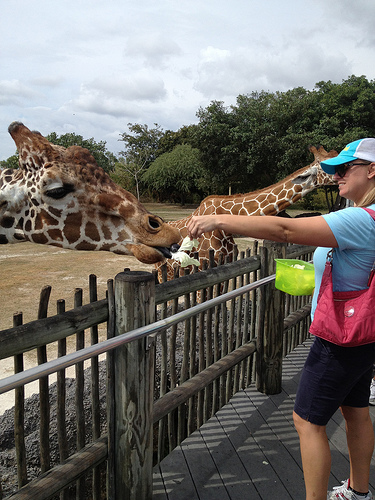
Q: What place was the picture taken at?
A: It was taken at the forest.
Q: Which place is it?
A: It is a forest.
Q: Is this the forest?
A: Yes, it is the forest.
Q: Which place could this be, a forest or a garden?
A: It is a forest.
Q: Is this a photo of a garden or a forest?
A: It is showing a forest.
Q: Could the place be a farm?
A: No, it is a forest.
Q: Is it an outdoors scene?
A: Yes, it is outdoors.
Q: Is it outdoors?
A: Yes, it is outdoors.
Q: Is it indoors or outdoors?
A: It is outdoors.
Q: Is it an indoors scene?
A: No, it is outdoors.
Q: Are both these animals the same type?
A: Yes, all the animals are giraffes.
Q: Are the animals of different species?
A: No, all the animals are giraffes.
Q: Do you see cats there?
A: No, there are no cats.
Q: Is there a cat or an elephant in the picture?
A: No, there are no cats or elephants.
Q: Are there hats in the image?
A: Yes, there is a hat.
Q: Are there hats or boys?
A: Yes, there is a hat.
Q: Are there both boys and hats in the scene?
A: No, there is a hat but no boys.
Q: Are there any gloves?
A: No, there are no gloves.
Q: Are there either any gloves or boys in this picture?
A: No, there are no gloves or boys.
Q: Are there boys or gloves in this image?
A: No, there are no gloves or boys.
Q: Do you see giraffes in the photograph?
A: Yes, there is a giraffe.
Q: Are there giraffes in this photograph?
A: Yes, there is a giraffe.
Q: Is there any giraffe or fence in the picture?
A: Yes, there is a giraffe.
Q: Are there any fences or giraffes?
A: Yes, there is a giraffe.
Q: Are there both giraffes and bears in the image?
A: No, there is a giraffe but no bears.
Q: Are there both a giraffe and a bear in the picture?
A: No, there is a giraffe but no bears.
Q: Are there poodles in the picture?
A: No, there are no poodles.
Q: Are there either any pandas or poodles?
A: No, there are no poodles or pandas.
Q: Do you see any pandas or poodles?
A: No, there are no poodles or pandas.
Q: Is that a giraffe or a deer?
A: That is a giraffe.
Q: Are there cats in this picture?
A: No, there are no cats.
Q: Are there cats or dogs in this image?
A: No, there are no cats or dogs.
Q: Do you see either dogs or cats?
A: No, there are no cats or dogs.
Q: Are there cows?
A: No, there are no cows.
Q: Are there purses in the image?
A: Yes, there is a purse.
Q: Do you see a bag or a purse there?
A: Yes, there is a purse.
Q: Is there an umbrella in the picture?
A: No, there are no umbrellas.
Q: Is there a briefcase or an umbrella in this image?
A: No, there are no umbrellas or briefcases.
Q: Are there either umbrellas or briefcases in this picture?
A: No, there are no umbrellas or briefcases.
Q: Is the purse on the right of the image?
A: Yes, the purse is on the right of the image.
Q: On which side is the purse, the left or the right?
A: The purse is on the right of the image.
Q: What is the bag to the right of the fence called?
A: The bag is a purse.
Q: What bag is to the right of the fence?
A: The bag is a purse.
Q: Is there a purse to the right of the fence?
A: Yes, there is a purse to the right of the fence.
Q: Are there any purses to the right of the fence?
A: Yes, there is a purse to the right of the fence.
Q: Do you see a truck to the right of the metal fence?
A: No, there is a purse to the right of the fence.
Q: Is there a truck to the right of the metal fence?
A: No, there is a purse to the right of the fence.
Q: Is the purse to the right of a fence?
A: Yes, the purse is to the right of a fence.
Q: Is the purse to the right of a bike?
A: No, the purse is to the right of a fence.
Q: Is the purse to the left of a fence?
A: No, the purse is to the right of a fence.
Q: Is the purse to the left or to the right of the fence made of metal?
A: The purse is to the right of the fence.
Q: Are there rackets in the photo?
A: No, there are no rackets.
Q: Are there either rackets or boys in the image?
A: No, there are no rackets or boys.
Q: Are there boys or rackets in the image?
A: No, there are no rackets or boys.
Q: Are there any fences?
A: Yes, there is a fence.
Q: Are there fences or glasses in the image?
A: Yes, there is a fence.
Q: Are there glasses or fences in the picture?
A: Yes, there is a fence.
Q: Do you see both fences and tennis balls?
A: No, there is a fence but no tennis balls.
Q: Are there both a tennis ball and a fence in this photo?
A: No, there is a fence but no tennis balls.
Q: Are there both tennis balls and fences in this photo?
A: No, there is a fence but no tennis balls.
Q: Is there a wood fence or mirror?
A: Yes, there is a wood fence.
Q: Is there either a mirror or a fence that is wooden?
A: Yes, the fence is wooden.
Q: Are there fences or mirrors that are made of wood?
A: Yes, the fence is made of wood.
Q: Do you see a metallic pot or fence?
A: Yes, there is a metal fence.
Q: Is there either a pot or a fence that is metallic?
A: Yes, the fence is metallic.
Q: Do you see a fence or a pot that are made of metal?
A: Yes, the fence is made of metal.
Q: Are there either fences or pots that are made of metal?
A: Yes, the fence is made of metal.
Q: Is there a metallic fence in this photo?
A: Yes, there is a metal fence.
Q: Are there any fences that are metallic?
A: Yes, there is a fence that is metallic.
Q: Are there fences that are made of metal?
A: Yes, there is a fence that is made of metal.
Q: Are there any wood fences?
A: Yes, there is a wood fence.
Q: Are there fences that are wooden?
A: Yes, there is a fence that is wooden.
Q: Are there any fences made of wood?
A: Yes, there is a fence that is made of wood.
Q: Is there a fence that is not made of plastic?
A: Yes, there is a fence that is made of wood.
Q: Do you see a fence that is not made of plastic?
A: Yes, there is a fence that is made of wood.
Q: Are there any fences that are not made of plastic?
A: Yes, there is a fence that is made of wood.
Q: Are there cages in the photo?
A: No, there are no cages.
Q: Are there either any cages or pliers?
A: No, there are no cages or pliers.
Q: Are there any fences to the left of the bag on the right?
A: Yes, there is a fence to the left of the purse.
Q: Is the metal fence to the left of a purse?
A: Yes, the fence is to the left of a purse.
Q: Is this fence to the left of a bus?
A: No, the fence is to the left of a purse.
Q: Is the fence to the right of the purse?
A: No, the fence is to the left of the purse.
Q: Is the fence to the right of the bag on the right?
A: No, the fence is to the left of the purse.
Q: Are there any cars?
A: No, there are no cars.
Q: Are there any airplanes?
A: No, there are no airplanes.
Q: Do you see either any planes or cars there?
A: No, there are no planes or cars.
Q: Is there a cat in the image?
A: No, there are no cats.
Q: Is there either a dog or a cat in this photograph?
A: No, there are no cats or dogs.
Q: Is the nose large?
A: Yes, the nose is large.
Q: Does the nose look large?
A: Yes, the nose is large.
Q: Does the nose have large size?
A: Yes, the nose is large.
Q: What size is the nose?
A: The nose is large.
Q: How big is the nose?
A: The nose is large.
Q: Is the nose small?
A: No, the nose is large.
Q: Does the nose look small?
A: No, the nose is large.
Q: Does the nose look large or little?
A: The nose is large.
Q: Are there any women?
A: Yes, there is a woman.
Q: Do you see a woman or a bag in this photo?
A: Yes, there is a woman.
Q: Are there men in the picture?
A: No, there are no men.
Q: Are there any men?
A: No, there are no men.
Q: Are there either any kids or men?
A: No, there are no men or kids.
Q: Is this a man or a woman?
A: This is a woman.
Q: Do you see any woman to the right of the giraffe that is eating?
A: Yes, there is a woman to the right of the giraffe.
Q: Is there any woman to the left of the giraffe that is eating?
A: No, the woman is to the right of the giraffe.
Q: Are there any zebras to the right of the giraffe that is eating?
A: No, there is a woman to the right of the giraffe.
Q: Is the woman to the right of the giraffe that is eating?
A: Yes, the woman is to the right of the giraffe.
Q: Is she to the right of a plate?
A: No, the woman is to the right of the giraffe.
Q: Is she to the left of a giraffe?
A: No, the woman is to the right of a giraffe.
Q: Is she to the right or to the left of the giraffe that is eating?
A: The woman is to the right of the giraffe.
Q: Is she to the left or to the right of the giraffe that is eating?
A: The woman is to the right of the giraffe.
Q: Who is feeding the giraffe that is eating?
A: The woman is feeding the giraffe.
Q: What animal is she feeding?
A: The woman is feeding the giraffe.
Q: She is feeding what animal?
A: The woman is feeding the giraffe.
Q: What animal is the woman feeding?
A: The woman is feeding the giraffe.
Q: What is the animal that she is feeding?
A: The animal is a giraffe.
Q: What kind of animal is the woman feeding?
A: The woman is feeding the giraffe.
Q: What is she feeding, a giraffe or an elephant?
A: The woman is feeding a giraffe.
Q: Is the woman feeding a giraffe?
A: Yes, the woman is feeding a giraffe.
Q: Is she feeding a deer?
A: No, the woman is feeding a giraffe.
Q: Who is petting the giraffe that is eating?
A: The woman is petting the giraffe.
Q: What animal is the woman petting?
A: The woman is petting the giraffe.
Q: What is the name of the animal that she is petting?
A: The animal is a giraffe.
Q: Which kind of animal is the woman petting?
A: The woman is petting the giraffe.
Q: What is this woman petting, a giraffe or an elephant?
A: The woman is petting a giraffe.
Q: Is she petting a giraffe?
A: Yes, the woman is petting a giraffe.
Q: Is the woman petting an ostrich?
A: No, the woman is petting a giraffe.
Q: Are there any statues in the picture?
A: No, there are no statues.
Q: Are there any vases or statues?
A: No, there are no statues or vases.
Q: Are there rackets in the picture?
A: No, there are no rackets.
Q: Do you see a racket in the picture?
A: No, there are no rackets.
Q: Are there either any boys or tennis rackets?
A: No, there are no tennis rackets or boys.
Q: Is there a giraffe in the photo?
A: Yes, there is a giraffe.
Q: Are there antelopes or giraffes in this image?
A: Yes, there is a giraffe.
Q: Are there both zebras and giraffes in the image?
A: No, there is a giraffe but no zebras.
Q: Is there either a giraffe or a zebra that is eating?
A: Yes, the giraffe is eating.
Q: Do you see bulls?
A: No, there are no bulls.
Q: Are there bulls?
A: No, there are no bulls.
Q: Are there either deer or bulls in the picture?
A: No, there are no bulls or deer.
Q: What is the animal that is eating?
A: The animal is a giraffe.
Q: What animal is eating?
A: The animal is a giraffe.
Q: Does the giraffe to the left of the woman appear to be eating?
A: Yes, the giraffe is eating.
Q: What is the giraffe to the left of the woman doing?
A: The giraffe is eating.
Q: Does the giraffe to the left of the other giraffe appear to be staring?
A: No, the giraffe is eating.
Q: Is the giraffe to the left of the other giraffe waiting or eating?
A: The giraffe is eating.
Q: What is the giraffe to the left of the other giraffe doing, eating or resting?
A: The giraffe is eating.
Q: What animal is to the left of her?
A: The animal is a giraffe.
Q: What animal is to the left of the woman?
A: The animal is a giraffe.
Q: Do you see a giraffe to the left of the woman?
A: Yes, there is a giraffe to the left of the woman.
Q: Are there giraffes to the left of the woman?
A: Yes, there is a giraffe to the left of the woman.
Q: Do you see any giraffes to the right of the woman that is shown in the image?
A: No, the giraffe is to the left of the woman.